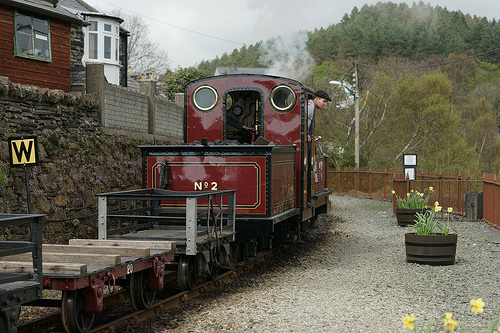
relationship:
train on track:
[137, 73, 329, 241] [1, 209, 320, 332]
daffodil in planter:
[407, 200, 454, 235] [405, 233, 457, 265]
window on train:
[193, 85, 219, 111] [137, 73, 329, 241]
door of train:
[302, 94, 314, 208] [137, 73, 329, 241]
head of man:
[313, 90, 331, 110] [307, 89, 331, 209]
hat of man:
[314, 89, 331, 100] [307, 89, 331, 209]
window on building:
[14, 15, 51, 61] [0, 0, 128, 89]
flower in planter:
[392, 185, 434, 210] [395, 208, 432, 226]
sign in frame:
[405, 155, 416, 165] [402, 152, 419, 167]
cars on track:
[0, 187, 236, 333] [1, 209, 320, 332]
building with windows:
[0, 0, 133, 93] [83, 19, 123, 63]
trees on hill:
[195, 0, 500, 78] [162, 14, 500, 178]